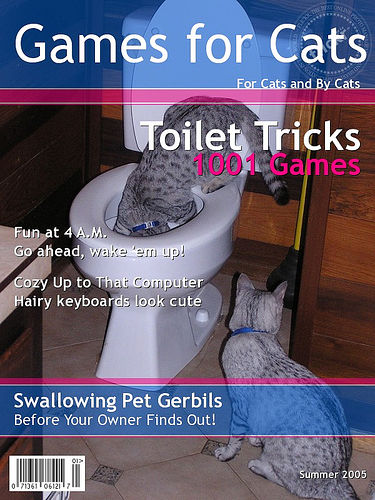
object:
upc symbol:
[5, 452, 86, 493]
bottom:
[0, 486, 374, 500]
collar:
[229, 323, 272, 341]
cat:
[213, 269, 360, 499]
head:
[127, 221, 172, 239]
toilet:
[62, 0, 261, 396]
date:
[297, 467, 368, 484]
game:
[14, 21, 146, 73]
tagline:
[12, 387, 223, 433]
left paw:
[213, 445, 227, 462]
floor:
[44, 260, 375, 500]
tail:
[239, 108, 292, 207]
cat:
[110, 94, 291, 237]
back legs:
[210, 135, 245, 190]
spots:
[260, 352, 304, 379]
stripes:
[257, 147, 285, 196]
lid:
[127, 0, 264, 172]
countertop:
[0, 224, 52, 326]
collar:
[131, 219, 160, 233]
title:
[5, 7, 373, 82]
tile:
[65, 408, 223, 492]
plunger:
[263, 77, 326, 315]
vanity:
[2, 290, 45, 499]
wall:
[0, 0, 105, 284]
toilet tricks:
[136, 113, 361, 153]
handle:
[292, 87, 320, 252]